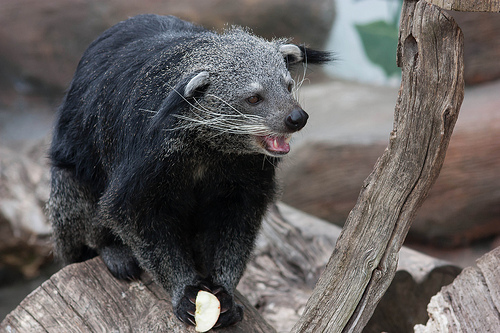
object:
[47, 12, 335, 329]
binturong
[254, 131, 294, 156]
mouth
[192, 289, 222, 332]
apple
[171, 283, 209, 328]
paws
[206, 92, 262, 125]
whiskers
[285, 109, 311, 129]
nose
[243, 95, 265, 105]
eye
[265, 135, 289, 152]
tongue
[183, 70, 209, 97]
ear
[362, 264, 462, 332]
shadow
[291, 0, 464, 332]
branch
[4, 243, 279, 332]
wood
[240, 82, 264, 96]
eyebrow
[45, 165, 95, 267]
tail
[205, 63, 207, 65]
sand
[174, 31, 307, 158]
head